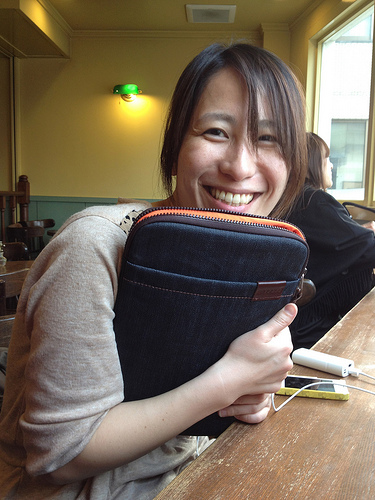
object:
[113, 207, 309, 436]
tablet case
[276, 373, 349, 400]
cellphone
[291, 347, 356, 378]
charger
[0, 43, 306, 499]
woman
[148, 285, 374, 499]
table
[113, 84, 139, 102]
light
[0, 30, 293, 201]
wall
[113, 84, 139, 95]
shade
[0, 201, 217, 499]
blouse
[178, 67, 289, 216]
face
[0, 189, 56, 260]
chair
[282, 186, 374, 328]
poncho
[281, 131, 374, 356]
woman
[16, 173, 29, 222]
rail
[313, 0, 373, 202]
window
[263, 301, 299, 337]
thumb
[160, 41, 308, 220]
hair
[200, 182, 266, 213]
grin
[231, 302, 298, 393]
hand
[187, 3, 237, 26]
vent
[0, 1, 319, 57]
ceiling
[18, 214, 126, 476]
sleeve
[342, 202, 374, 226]
bag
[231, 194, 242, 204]
teeth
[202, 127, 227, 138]
eye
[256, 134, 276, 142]
eye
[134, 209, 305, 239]
lining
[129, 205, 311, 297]
zipper